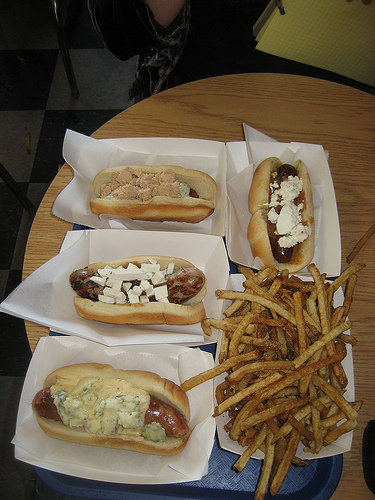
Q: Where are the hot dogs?
A: On Tray.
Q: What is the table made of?
A: Wood.